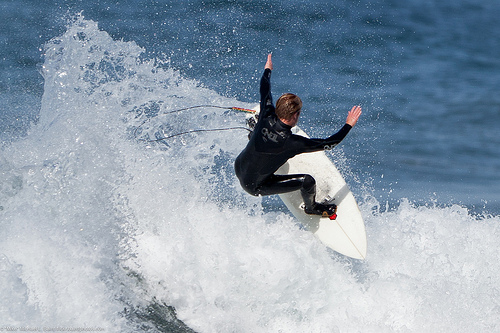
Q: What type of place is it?
A: It is an ocean.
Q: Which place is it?
A: It is an ocean.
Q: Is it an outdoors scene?
A: Yes, it is outdoors.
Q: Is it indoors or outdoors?
A: It is outdoors.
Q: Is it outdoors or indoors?
A: It is outdoors.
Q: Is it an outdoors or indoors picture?
A: It is outdoors.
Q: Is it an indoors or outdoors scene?
A: It is outdoors.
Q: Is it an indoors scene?
A: No, it is outdoors.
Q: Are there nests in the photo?
A: No, there are no nests.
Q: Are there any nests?
A: No, there are no nests.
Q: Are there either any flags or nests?
A: No, there are no nests or flags.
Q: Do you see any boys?
A: No, there are no boys.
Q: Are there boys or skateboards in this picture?
A: No, there are no boys or skateboards.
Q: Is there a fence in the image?
A: No, there are no fences.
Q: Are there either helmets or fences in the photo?
A: No, there are no fences or helmets.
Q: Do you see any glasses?
A: No, there are no glasses.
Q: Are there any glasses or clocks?
A: No, there are no glasses or clocks.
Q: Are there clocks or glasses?
A: No, there are no glasses or clocks.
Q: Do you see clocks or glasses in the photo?
A: No, there are no glasses or clocks.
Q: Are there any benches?
A: No, there are no benches.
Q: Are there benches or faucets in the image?
A: No, there are no benches or faucets.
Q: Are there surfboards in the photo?
A: Yes, there is a surfboard.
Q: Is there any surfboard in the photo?
A: Yes, there is a surfboard.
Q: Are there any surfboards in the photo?
A: Yes, there is a surfboard.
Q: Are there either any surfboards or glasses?
A: Yes, there is a surfboard.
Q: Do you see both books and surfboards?
A: No, there is a surfboard but no books.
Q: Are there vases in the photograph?
A: No, there are no vases.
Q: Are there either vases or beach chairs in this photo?
A: No, there are no vases or beach chairs.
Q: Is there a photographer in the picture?
A: No, there are no photographers.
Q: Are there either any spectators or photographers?
A: No, there are no photographers or spectators.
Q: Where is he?
A: The man is in the ocean.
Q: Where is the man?
A: The man is in the ocean.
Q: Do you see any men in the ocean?
A: Yes, there is a man in the ocean.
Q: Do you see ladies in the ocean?
A: No, there is a man in the ocean.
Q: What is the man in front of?
A: The man is in front of the ocean.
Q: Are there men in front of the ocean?
A: Yes, there is a man in front of the ocean.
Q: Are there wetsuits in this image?
A: Yes, there is a wetsuit.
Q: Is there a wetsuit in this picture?
A: Yes, there is a wetsuit.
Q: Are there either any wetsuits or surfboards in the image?
A: Yes, there is a wetsuit.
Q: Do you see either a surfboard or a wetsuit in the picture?
A: Yes, there is a wetsuit.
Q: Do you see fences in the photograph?
A: No, there are no fences.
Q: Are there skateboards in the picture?
A: No, there are no skateboards.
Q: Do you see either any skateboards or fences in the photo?
A: No, there are no skateboards or fences.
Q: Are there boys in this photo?
A: No, there are no boys.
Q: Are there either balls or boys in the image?
A: No, there are no boys or balls.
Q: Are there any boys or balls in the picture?
A: No, there are no boys or balls.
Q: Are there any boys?
A: No, there are no boys.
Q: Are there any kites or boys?
A: No, there are no boys or kites.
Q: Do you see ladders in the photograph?
A: No, there are no ladders.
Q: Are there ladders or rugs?
A: No, there are no ladders or rugs.